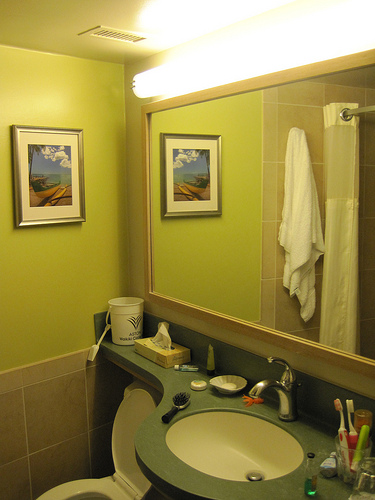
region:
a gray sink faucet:
[243, 352, 305, 413]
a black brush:
[159, 388, 194, 423]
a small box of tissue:
[128, 320, 191, 365]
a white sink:
[169, 407, 300, 483]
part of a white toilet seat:
[34, 387, 156, 498]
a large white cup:
[105, 292, 143, 344]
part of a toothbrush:
[345, 398, 363, 464]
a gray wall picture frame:
[8, 125, 89, 228]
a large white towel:
[278, 126, 333, 323]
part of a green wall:
[26, 232, 125, 301]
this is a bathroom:
[21, 27, 363, 495]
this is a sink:
[149, 384, 299, 498]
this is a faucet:
[239, 342, 312, 420]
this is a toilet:
[40, 367, 196, 498]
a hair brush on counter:
[158, 374, 199, 448]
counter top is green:
[118, 333, 341, 498]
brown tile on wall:
[10, 385, 106, 462]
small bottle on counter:
[298, 436, 325, 496]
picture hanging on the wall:
[7, 119, 90, 232]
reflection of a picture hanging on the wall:
[153, 130, 228, 222]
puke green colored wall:
[0, 38, 139, 382]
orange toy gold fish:
[240, 391, 267, 411]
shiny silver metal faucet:
[244, 345, 304, 430]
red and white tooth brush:
[332, 393, 349, 480]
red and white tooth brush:
[344, 396, 363, 472]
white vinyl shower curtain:
[317, 95, 365, 365]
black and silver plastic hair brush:
[158, 386, 196, 429]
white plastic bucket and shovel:
[79, 294, 147, 367]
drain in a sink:
[242, 468, 266, 484]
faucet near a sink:
[242, 351, 302, 423]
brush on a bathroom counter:
[154, 385, 188, 420]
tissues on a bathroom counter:
[128, 315, 189, 363]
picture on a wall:
[4, 116, 87, 228]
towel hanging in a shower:
[273, 121, 324, 323]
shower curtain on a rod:
[311, 94, 365, 357]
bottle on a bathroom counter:
[300, 447, 319, 494]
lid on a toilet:
[107, 385, 158, 499]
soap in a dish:
[218, 379, 240, 393]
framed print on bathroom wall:
[10, 125, 86, 226]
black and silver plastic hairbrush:
[161, 389, 190, 423]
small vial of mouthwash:
[303, 452, 317, 495]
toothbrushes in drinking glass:
[333, 399, 371, 485]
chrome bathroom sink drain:
[246, 470, 264, 481]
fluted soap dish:
[209, 373, 247, 394]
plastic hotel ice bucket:
[106, 296, 145, 346]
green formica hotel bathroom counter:
[94, 310, 374, 499]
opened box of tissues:
[133, 321, 189, 369]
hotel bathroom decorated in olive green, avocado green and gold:
[7, 88, 373, 498]